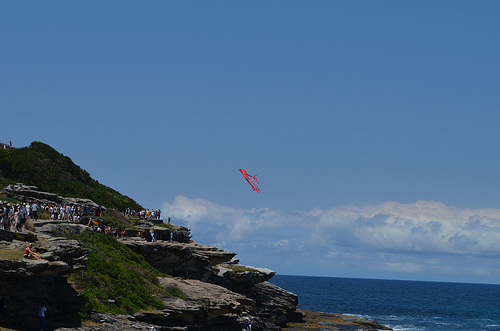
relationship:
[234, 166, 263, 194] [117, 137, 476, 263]
kite flying in air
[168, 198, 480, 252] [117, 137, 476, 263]
clouds floating in air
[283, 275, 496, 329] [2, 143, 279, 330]
ocean next to hill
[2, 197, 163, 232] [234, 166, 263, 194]
people watching kite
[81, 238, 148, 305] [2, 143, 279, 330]
grass on hill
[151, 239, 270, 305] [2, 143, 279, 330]
rocks sticking in hill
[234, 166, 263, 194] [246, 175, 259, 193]
kite has tail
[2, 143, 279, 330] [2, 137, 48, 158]
hill has top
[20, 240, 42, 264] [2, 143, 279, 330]
person sitting on hill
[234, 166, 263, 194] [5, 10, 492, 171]
kite in sky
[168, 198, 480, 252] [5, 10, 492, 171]
clouds in sky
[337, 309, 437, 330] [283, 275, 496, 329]
wave in ocean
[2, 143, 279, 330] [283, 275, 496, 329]
hill in front of ocean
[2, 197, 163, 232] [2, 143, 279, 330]
people in hill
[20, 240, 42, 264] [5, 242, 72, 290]
person sitting on rock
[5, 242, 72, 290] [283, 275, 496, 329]
rock facing ocean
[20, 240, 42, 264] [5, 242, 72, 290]
person in rock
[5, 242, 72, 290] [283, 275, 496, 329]
rock in front of ocean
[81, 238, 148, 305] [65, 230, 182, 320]
grass covers rock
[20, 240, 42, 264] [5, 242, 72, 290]
person on rock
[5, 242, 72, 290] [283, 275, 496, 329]
rock away from ocean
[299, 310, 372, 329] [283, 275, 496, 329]
plateau in front of ocean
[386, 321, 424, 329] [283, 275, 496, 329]
foam in ocean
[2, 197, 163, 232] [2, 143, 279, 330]
people on top of hill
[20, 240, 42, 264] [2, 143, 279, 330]
person laying on top of hill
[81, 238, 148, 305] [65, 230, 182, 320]
grass on rock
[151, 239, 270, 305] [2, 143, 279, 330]
rocks jettisoned from hill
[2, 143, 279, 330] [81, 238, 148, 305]
hill mixed with grass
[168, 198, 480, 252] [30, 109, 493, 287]
clouds in background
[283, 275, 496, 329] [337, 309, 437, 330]
ocean breaking from wave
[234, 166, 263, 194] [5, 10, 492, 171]
kite flying in sky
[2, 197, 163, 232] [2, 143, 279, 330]
people standing on hill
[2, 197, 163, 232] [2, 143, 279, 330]
people on hill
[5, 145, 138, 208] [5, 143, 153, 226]
forest on hill top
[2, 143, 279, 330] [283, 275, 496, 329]
hill over ocean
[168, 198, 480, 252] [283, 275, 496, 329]
clouds over ocean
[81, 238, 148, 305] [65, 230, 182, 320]
grass growing on rock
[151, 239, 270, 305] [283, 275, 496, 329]
rocks over ocean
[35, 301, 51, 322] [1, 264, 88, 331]
man in cave